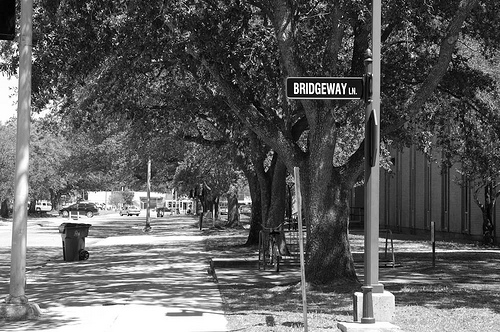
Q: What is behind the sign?
A: Tree.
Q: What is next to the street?
A: Sidewalk.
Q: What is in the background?
A: Houses.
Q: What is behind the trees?
A: Fence.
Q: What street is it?
A: Bridgeway Ln.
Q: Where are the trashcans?
A: On the sidewalk.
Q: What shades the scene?
A: Trees.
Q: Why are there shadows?
A: From the trees.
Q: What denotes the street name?
A: A sign.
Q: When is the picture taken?
A: In the daytime.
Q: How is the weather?
A: Sunny.